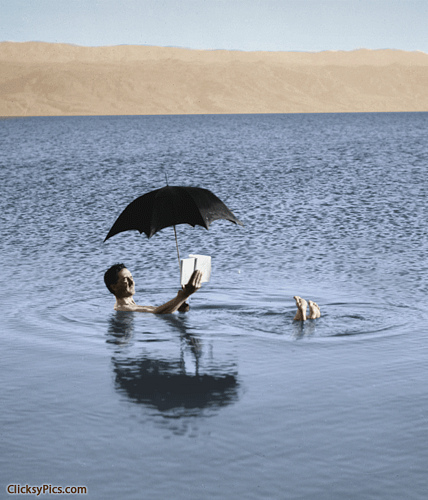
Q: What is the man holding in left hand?
A: Umbrella.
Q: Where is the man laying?
A: In the water.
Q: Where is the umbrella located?
A: Above the man.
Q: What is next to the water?
A: Brown sand.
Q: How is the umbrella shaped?
A: Circle.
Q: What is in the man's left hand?
A: Book.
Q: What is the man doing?
A: Floating in the water.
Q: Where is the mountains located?
A: Behind the water.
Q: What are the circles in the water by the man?
A: Ripples.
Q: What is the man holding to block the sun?
A: An umbrella.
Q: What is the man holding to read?
A: A book.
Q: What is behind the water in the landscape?
A: Brown hillside.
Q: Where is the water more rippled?
A: Behind the man.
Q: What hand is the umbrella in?
A: Left.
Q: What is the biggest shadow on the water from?
A: Umbrella.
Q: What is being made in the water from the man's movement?
A: Ripples.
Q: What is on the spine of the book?
A: The man's fingers.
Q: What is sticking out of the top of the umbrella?
A: The tip of the handle.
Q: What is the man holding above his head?
A: Umbrellas.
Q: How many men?
A: One.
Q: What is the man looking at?
A: Book.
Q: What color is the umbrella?
A: Black.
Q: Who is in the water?
A: A man.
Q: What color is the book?
A: White.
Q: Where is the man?
A: In the water.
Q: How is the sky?
A: Clear.